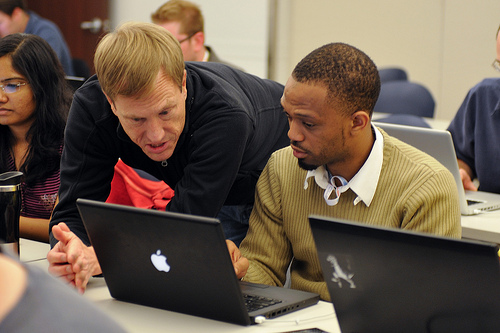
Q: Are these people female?
A: No, they are both male and female.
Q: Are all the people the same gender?
A: No, they are both male and female.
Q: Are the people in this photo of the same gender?
A: No, they are both male and female.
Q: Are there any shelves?
A: No, there are no shelves.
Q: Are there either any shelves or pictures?
A: No, there are no shelves or pictures.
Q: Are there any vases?
A: No, there are no vases.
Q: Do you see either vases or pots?
A: No, there are no vases or pots.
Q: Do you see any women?
A: Yes, there is a woman.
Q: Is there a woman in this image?
A: Yes, there is a woman.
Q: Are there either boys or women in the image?
A: Yes, there is a woman.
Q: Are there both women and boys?
A: No, there is a woman but no boys.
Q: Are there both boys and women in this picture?
A: No, there is a woman but no boys.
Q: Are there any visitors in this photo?
A: No, there are no visitors.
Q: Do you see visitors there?
A: No, there are no visitors.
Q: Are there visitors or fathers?
A: No, there are no visitors or fathers.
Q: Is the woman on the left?
A: Yes, the woman is on the left of the image.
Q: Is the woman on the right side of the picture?
A: No, the woman is on the left of the image.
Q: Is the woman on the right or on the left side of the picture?
A: The woman is on the left of the image.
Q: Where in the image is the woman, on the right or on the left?
A: The woman is on the left of the image.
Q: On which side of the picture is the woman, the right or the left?
A: The woman is on the left of the image.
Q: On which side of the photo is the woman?
A: The woman is on the left of the image.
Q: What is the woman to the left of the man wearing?
A: The woman is wearing glasses.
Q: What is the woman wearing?
A: The woman is wearing glasses.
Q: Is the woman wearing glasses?
A: Yes, the woman is wearing glasses.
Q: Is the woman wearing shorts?
A: No, the woman is wearing glasses.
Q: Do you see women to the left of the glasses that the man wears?
A: Yes, there is a woman to the left of the glasses.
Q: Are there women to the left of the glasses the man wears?
A: Yes, there is a woman to the left of the glasses.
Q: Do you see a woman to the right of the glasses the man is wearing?
A: No, the woman is to the left of the glasses.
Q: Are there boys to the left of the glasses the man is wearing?
A: No, there is a woman to the left of the glasses.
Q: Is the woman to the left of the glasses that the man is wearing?
A: Yes, the woman is to the left of the glasses.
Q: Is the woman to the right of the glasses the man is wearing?
A: No, the woman is to the left of the glasses.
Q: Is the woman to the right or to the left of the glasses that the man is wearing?
A: The woman is to the left of the glasses.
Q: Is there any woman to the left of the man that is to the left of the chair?
A: Yes, there is a woman to the left of the man.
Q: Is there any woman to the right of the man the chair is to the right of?
A: No, the woman is to the left of the man.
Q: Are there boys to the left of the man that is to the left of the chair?
A: No, there is a woman to the left of the man.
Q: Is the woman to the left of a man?
A: Yes, the woman is to the left of a man.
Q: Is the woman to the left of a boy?
A: No, the woman is to the left of a man.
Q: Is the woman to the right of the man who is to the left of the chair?
A: No, the woman is to the left of the man.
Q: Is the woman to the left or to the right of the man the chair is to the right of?
A: The woman is to the left of the man.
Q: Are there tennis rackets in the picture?
A: No, there are no tennis rackets.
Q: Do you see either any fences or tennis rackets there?
A: No, there are no tennis rackets or fences.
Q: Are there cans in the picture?
A: No, there are no cans.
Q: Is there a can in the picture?
A: No, there are no cans.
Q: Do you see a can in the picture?
A: No, there are no cans.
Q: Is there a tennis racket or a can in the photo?
A: No, there are no cans or rackets.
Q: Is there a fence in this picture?
A: No, there are no fences.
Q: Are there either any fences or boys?
A: No, there are no fences or boys.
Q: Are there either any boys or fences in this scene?
A: No, there are no fences or boys.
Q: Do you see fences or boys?
A: No, there are no fences or boys.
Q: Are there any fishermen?
A: No, there are no fishermen.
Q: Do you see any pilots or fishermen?
A: No, there are no fishermen or pilots.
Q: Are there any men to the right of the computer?
A: Yes, there is a man to the right of the computer.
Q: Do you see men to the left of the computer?
A: No, the man is to the right of the computer.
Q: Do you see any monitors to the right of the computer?
A: No, there is a man to the right of the computer.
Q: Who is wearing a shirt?
A: The man is wearing a shirt.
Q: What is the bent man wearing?
A: The man is wearing a shirt.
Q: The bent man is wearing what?
A: The man is wearing a shirt.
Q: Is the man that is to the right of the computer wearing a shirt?
A: Yes, the man is wearing a shirt.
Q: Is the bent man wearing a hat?
A: No, the man is wearing a shirt.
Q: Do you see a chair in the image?
A: Yes, there is a chair.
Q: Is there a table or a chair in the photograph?
A: Yes, there is a chair.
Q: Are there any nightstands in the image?
A: No, there are no nightstands.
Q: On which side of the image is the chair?
A: The chair is on the right of the image.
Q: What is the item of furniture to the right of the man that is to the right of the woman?
A: The piece of furniture is a chair.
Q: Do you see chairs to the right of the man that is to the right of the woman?
A: Yes, there is a chair to the right of the man.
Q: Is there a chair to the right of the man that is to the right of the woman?
A: Yes, there is a chair to the right of the man.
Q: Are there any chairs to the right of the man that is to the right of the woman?
A: Yes, there is a chair to the right of the man.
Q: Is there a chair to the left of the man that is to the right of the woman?
A: No, the chair is to the right of the man.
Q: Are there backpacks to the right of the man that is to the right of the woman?
A: No, there is a chair to the right of the man.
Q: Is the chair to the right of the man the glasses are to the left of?
A: Yes, the chair is to the right of the man.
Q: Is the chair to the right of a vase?
A: No, the chair is to the right of the man.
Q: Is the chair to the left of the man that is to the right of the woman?
A: No, the chair is to the right of the man.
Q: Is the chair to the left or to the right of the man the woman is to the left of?
A: The chair is to the right of the man.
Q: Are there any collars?
A: Yes, there is a collar.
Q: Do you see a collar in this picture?
A: Yes, there is a collar.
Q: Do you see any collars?
A: Yes, there is a collar.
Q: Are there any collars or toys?
A: Yes, there is a collar.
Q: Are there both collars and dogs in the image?
A: No, there is a collar but no dogs.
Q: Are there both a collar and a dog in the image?
A: No, there is a collar but no dogs.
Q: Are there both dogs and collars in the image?
A: No, there is a collar but no dogs.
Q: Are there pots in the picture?
A: No, there are no pots.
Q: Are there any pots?
A: No, there are no pots.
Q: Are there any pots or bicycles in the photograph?
A: No, there are no pots or bicycles.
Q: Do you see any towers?
A: No, there are no towers.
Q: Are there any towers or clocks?
A: No, there are no towers or clocks.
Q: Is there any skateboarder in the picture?
A: No, there are no skateboarders.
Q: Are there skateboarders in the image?
A: No, there are no skateboarders.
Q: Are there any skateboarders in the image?
A: No, there are no skateboarders.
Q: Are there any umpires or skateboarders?
A: No, there are no skateboarders or umpires.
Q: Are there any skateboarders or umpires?
A: No, there are no skateboarders or umpires.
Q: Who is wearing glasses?
A: The man is wearing glasses.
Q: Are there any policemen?
A: No, there are no policemen.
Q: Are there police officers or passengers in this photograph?
A: No, there are no police officers or passengers.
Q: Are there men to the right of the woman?
A: Yes, there is a man to the right of the woman.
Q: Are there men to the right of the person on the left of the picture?
A: Yes, there is a man to the right of the woman.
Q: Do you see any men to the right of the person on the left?
A: Yes, there is a man to the right of the woman.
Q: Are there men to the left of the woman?
A: No, the man is to the right of the woman.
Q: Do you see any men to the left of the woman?
A: No, the man is to the right of the woman.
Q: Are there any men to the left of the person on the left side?
A: No, the man is to the right of the woman.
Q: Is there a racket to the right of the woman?
A: No, there is a man to the right of the woman.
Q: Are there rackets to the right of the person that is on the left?
A: No, there is a man to the right of the woman.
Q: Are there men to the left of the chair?
A: Yes, there is a man to the left of the chair.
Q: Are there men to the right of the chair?
A: No, the man is to the left of the chair.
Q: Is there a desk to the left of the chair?
A: No, there is a man to the left of the chair.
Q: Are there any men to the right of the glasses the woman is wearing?
A: Yes, there is a man to the right of the glasses.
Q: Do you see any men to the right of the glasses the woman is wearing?
A: Yes, there is a man to the right of the glasses.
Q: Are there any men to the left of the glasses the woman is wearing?
A: No, the man is to the right of the glasses.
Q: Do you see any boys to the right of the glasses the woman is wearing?
A: No, there is a man to the right of the glasses.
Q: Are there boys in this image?
A: No, there are no boys.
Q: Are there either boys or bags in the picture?
A: No, there are no boys or bags.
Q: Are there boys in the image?
A: No, there are no boys.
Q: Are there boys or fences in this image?
A: No, there are no boys or fences.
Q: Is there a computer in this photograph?
A: Yes, there is a computer.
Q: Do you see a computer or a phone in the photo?
A: Yes, there is a computer.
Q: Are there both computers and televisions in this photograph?
A: No, there is a computer but no televisions.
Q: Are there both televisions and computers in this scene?
A: No, there is a computer but no televisions.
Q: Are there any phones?
A: No, there are no phones.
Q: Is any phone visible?
A: No, there are no phones.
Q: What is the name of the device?
A: The device is a computer.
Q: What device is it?
A: The device is a computer.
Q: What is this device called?
A: This is a computer.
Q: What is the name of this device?
A: This is a computer.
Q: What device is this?
A: This is a computer.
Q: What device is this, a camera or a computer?
A: This is a computer.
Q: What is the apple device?
A: The device is a computer.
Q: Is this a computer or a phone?
A: This is a computer.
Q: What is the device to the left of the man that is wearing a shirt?
A: The device is a computer.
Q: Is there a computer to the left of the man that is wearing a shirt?
A: Yes, there is a computer to the left of the man.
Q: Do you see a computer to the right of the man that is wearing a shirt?
A: No, the computer is to the left of the man.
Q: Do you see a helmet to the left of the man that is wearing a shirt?
A: No, there is a computer to the left of the man.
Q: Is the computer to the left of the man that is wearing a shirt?
A: Yes, the computer is to the left of the man.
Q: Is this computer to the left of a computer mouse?
A: No, the computer is to the left of the man.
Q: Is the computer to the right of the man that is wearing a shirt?
A: No, the computer is to the left of the man.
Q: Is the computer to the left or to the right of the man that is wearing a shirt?
A: The computer is to the left of the man.